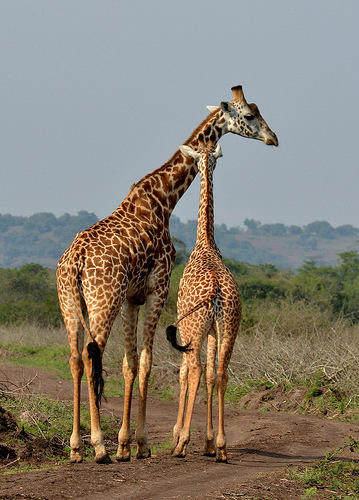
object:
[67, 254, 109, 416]
tail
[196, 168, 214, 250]
neck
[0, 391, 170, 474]
grass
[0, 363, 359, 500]
dirt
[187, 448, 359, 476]
shade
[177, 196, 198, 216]
clouds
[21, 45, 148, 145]
clouds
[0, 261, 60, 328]
bush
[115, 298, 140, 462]
legs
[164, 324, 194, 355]
hair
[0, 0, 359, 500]
poster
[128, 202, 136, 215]
brown spot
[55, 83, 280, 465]
adult giraffe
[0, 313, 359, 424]
grass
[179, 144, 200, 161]
ear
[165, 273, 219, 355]
tail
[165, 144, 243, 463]
giraffe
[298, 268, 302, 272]
foliage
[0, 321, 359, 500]
ground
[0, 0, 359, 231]
blue sky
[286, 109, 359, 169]
white clouds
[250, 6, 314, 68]
white clouds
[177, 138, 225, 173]
head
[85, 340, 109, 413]
hair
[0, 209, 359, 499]
wasteland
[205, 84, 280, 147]
head